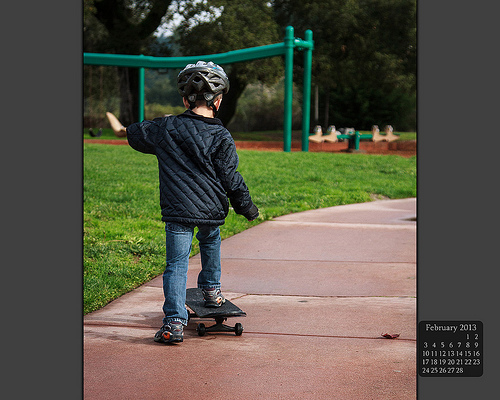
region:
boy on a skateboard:
[169, 275, 259, 337]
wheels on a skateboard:
[192, 323, 254, 336]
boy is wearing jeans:
[152, 195, 243, 329]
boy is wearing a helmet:
[167, 53, 235, 110]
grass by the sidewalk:
[275, 163, 381, 198]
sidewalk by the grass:
[82, 198, 417, 398]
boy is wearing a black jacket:
[120, 110, 252, 228]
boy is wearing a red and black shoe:
[149, 315, 198, 346]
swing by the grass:
[84, 58, 106, 150]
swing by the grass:
[109, 62, 131, 139]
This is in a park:
[41, 11, 422, 397]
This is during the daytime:
[64, 11, 436, 398]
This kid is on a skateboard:
[161, 276, 293, 342]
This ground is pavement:
[267, 248, 381, 391]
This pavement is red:
[250, 243, 413, 385]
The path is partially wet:
[237, 239, 419, 394]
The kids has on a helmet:
[158, 56, 238, 131]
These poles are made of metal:
[233, 32, 362, 140]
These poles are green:
[258, 17, 318, 173]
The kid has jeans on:
[147, 186, 212, 308]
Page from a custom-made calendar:
[0, 0, 499, 399]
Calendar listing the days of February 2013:
[417, 320, 481, 377]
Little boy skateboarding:
[106, 62, 265, 343]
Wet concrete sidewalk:
[264, 220, 414, 397]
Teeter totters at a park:
[308, 125, 398, 155]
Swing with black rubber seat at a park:
[86, 53, 104, 139]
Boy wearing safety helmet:
[177, 60, 227, 117]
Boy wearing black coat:
[126, 113, 258, 223]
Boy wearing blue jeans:
[162, 221, 223, 321]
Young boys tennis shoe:
[151, 318, 186, 343]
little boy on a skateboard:
[108, 51, 276, 349]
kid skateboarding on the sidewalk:
[122, 49, 276, 361]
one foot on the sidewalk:
[143, 278, 195, 348]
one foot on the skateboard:
[189, 259, 229, 313]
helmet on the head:
[169, 56, 239, 116]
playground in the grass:
[79, 33, 414, 165]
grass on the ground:
[85, 141, 432, 317]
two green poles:
[278, 25, 317, 153]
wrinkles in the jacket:
[161, 150, 224, 210]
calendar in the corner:
[419, 316, 488, 381]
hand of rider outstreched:
[103, 111, 160, 150]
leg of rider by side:
[197, 222, 229, 305]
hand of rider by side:
[217, 135, 259, 219]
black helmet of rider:
[180, 58, 227, 100]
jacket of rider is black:
[125, 120, 250, 222]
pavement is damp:
[87, 205, 415, 399]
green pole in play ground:
[82, 32, 324, 146]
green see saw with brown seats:
[300, 125, 397, 148]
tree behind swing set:
[75, 0, 279, 137]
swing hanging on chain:
[87, 123, 103, 138]